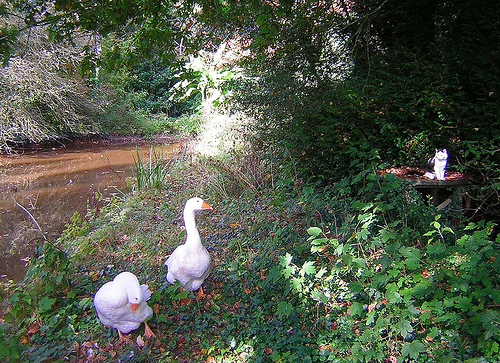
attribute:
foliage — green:
[269, 179, 499, 359]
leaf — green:
[36, 294, 58, 313]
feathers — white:
[159, 195, 214, 290]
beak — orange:
[198, 199, 213, 212]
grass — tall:
[90, 130, 189, 201]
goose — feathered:
[144, 185, 230, 297]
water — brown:
[3, 138, 243, 296]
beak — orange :
[197, 194, 221, 224]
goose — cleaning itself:
[138, 186, 232, 303]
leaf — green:
[378, 224, 403, 244]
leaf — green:
[401, 241, 421, 268]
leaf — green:
[383, 267, 408, 283]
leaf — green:
[381, 284, 411, 311]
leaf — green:
[431, 264, 458, 287]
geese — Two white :
[95, 192, 239, 328]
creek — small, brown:
[2, 133, 169, 235]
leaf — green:
[272, 301, 294, 317]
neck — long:
[182, 205, 205, 248]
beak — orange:
[199, 199, 217, 216]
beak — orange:
[127, 301, 139, 318]